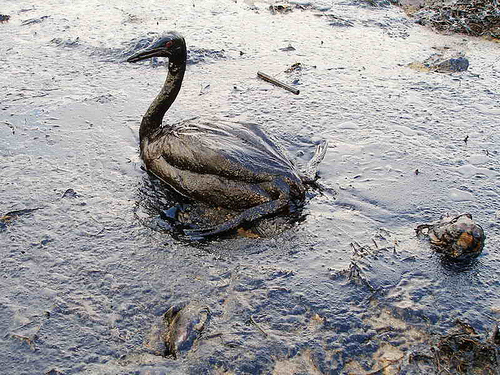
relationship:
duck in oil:
[122, 29, 311, 241] [2, 1, 497, 370]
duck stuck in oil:
[122, 29, 311, 241] [2, 1, 497, 370]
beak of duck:
[125, 44, 160, 65] [122, 29, 311, 241]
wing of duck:
[162, 132, 264, 185] [122, 29, 311, 241]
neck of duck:
[142, 64, 186, 126] [122, 29, 311, 241]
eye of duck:
[165, 39, 175, 50] [122, 29, 311, 241]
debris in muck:
[6, 14, 482, 357] [1, 4, 497, 373]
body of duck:
[148, 115, 275, 211] [122, 29, 311, 241]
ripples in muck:
[21, 17, 482, 337] [1, 4, 497, 373]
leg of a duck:
[175, 190, 291, 244] [122, 29, 311, 241]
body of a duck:
[148, 115, 304, 209] [122, 29, 311, 241]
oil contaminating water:
[2, 1, 497, 370] [2, 6, 496, 371]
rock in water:
[152, 295, 219, 353] [2, 6, 496, 371]